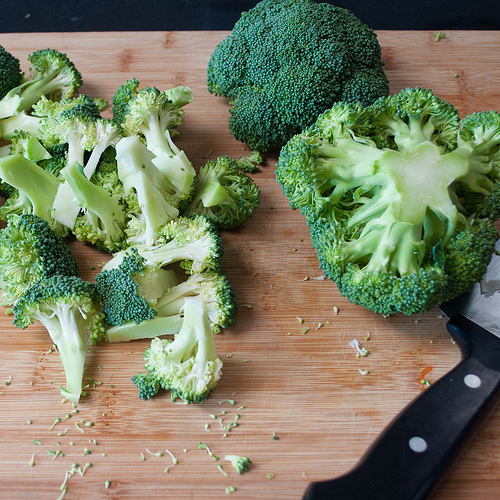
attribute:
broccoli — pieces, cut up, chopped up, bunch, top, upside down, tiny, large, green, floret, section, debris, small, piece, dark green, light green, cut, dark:
[10, 39, 498, 347]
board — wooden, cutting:
[3, 33, 498, 497]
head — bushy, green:
[225, 25, 394, 108]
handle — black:
[319, 317, 496, 499]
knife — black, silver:
[290, 215, 496, 498]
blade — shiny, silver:
[437, 241, 498, 308]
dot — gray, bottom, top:
[399, 429, 435, 465]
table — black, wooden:
[19, 5, 479, 26]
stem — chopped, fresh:
[36, 322, 97, 398]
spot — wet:
[247, 294, 380, 397]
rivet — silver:
[398, 430, 456, 466]